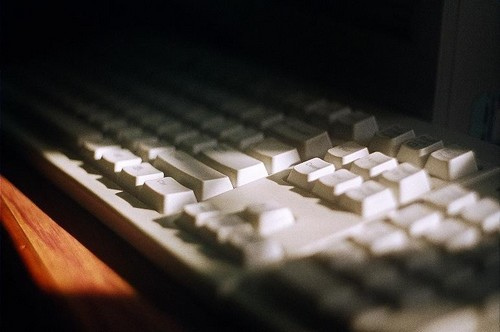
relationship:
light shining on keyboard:
[257, 194, 308, 214] [50, 57, 470, 328]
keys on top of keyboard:
[83, 75, 199, 141] [50, 57, 470, 328]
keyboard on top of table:
[50, 57, 470, 328] [33, 219, 122, 268]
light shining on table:
[257, 194, 308, 214] [33, 219, 122, 268]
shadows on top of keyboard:
[97, 52, 283, 135] [50, 57, 470, 328]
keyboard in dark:
[50, 57, 470, 328] [12, 42, 174, 105]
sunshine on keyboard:
[307, 287, 325, 297] [50, 57, 470, 328]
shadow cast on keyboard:
[176, 8, 204, 23] [50, 57, 470, 328]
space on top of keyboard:
[3, 94, 83, 153] [50, 57, 470, 328]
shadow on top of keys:
[176, 8, 204, 23] [83, 75, 199, 141]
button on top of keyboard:
[235, 154, 271, 176] [50, 57, 470, 328]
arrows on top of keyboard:
[192, 215, 262, 255] [50, 57, 470, 328]